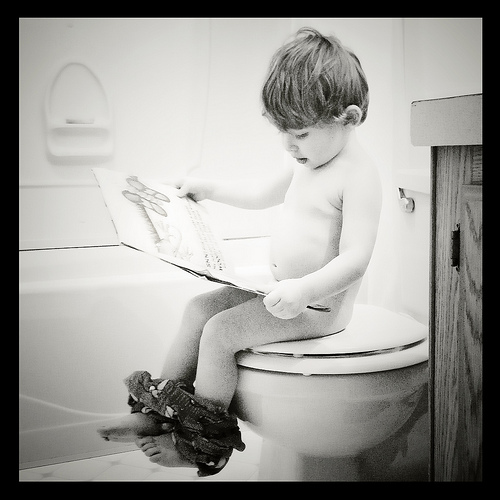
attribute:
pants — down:
[120, 365, 252, 478]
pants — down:
[68, 351, 240, 481]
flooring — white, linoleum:
[16, 423, 431, 480]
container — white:
[38, 51, 124, 183]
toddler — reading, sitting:
[89, 24, 391, 476]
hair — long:
[252, 24, 374, 134]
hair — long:
[261, 25, 370, 127]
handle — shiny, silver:
[390, 184, 418, 216]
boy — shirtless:
[143, 51, 433, 365]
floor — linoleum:
[44, 458, 186, 491]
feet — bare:
[86, 402, 210, 468]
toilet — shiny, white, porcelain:
[186, 165, 431, 480]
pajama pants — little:
[121, 375, 241, 471]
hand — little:
[257, 277, 305, 319]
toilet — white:
[231, 175, 428, 480]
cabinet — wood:
[414, 111, 486, 483]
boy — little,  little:
[93, 28, 387, 468]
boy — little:
[145, 32, 392, 469]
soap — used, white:
[58, 107, 106, 134]